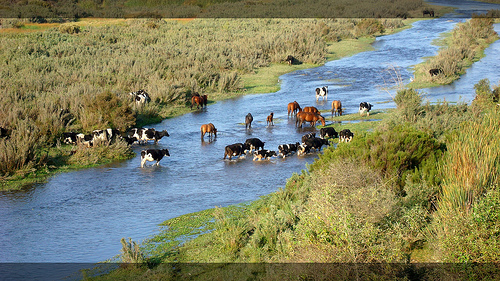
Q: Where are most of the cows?
A: In river.